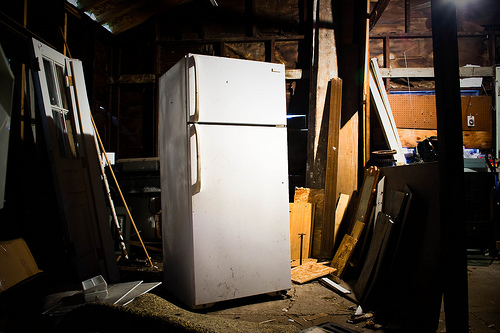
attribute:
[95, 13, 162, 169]
building — wood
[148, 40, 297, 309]
fridge — white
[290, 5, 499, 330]
work area — lighted wood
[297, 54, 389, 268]
pieces — lumber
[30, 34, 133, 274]
door — white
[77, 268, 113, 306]
ice trays — white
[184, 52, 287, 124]
freezer door — close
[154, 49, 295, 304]
fridge — dirty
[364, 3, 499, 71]
wall — wooden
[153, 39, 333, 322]
refrigerator — white 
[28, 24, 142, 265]
door — white , old 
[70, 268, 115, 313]
ice makers — white , plastic 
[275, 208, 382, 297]
fiberboard — leftover pieces  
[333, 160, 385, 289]
mirror — discarded , wood , framed , leaning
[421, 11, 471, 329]
column — lolly 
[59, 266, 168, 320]
boards — discarded , white , plastic 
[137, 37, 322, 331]
refrigerator — old , white 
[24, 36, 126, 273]
door — old, white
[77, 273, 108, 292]
icecube trays — white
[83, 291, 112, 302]
icecube trays — white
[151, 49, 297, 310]
refrigerator — old fashioned, white, large, dilapitated , old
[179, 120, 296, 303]
door — closed, white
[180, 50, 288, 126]
door — white, old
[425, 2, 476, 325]
beam — wooden, support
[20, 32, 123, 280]
door — old, white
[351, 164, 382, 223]
framed mirror — brown, wooden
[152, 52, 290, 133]
freezer — small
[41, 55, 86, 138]
window — paneled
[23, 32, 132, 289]
door — white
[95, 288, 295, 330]
carpet padding — folded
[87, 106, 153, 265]
handle — wooden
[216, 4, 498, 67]
wall — non-insulated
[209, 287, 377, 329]
floor — dirty, cracked, concrete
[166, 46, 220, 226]
handle — white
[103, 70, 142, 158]
wood — brown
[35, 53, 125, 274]
door — white